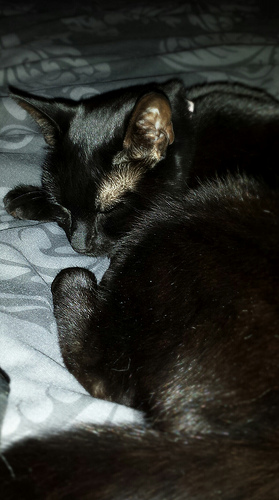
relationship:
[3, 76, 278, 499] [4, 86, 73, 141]
cat has ear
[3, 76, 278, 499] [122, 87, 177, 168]
cat has ear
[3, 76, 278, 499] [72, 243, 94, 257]
cat has nose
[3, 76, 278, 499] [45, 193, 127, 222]
cat has eyes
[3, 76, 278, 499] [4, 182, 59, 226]
cat has paw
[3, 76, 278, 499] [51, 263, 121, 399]
cat has foot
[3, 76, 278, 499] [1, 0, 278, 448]
cat on blanket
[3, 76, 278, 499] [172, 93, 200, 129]
cat has collar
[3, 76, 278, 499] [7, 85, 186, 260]
cat has head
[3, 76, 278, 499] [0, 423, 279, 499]
cat has tail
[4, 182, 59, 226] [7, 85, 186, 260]
paw next to head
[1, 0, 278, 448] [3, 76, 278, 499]
blanket under cat